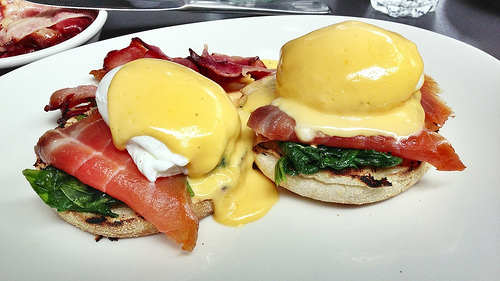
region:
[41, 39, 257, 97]
strips of bacon on white plate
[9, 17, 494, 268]
white plate food is on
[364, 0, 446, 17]
glass on corner of table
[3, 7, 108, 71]
white plate abutting foreground white plate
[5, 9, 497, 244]
table white plates are on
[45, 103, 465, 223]
slices of meat on open faced sandwich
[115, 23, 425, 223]
yellow sauce on food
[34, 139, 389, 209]
green leaves underneath meat slices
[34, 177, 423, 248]
bottom of open faced sandwiches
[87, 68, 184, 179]
white food on top of meat slice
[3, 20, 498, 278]
breakfast covered in sauce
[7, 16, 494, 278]
food on white plate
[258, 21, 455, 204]
food on english muffin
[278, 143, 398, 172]
cooked green spinach leaves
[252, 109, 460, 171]
slice of fish under sauce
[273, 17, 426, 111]
yellow sauce on mound of foord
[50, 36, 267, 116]
pile of cooked bacon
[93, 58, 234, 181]
yellow sauce on egg whites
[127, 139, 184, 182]
corner of folded egg white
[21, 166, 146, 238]
spinach on muffin top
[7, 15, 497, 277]
food on a plate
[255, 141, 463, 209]
an English muffin on the plate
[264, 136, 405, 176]
spinach on the muffin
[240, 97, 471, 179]
salmon on the muffin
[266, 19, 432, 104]
an egg on top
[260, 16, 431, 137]
the egg is covered in sauce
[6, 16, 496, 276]
the plate is white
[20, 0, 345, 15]
a knife behind the plate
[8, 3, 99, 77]
a dish to the left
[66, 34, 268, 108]
bacon on the plate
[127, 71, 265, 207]
melted cheese dripping down to the plate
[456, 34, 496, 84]
edge of a white plate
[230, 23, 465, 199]
food sitting on a plate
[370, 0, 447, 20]
bottom of a glass on the table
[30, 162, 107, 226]
lettuce on a sandwich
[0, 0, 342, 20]
silver knife leaning against a bowl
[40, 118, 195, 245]
very thin sliced meat on a sandwich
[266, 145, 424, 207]
bread at the bottom of a sandwich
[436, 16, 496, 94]
white plate sitting on a table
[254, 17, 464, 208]
sandwich sitting on a plate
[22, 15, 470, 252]
the breakfast is eggs benedict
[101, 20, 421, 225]
yellow hollandaise sauce is on the eggs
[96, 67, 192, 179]
poached eggs are underneath the sauce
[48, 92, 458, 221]
slices of ham are under the eggs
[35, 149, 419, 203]
spinach leaves are under the eggs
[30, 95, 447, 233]
all the ingredients are on english muffins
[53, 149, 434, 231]
the english muffins are toasted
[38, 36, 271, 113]
bacon is on the side of the plate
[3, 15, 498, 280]
the plate is oval and white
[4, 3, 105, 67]
a white bowl is on the side of the eggs